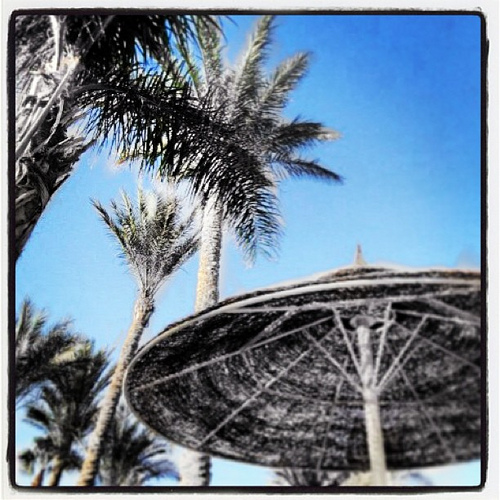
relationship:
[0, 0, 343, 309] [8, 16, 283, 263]
tree next to tree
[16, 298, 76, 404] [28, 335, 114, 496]
palm tree next to palm tree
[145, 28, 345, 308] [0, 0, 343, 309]
tree next to tree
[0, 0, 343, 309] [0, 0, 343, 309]
tree next to tree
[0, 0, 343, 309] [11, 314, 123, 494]
tree next to tree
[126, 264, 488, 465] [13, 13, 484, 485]
umbrella under sky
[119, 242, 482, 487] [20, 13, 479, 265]
umbrella under blue sky